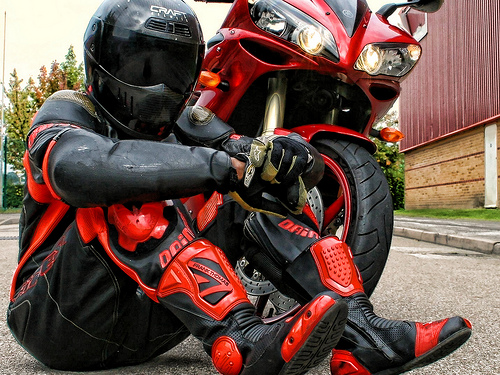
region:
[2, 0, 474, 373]
a very protective suit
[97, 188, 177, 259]
a substantial knee pad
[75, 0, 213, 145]
a helmet that could be a mask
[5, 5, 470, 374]
a person in Halloween colors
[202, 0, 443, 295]
a cycle with its light on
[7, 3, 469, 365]
color coordinated bike and outfit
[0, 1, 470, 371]
a bike rider sits on the pavement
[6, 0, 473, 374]
a motorcycle rider takes a break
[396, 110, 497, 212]
a foundation of unfinished wood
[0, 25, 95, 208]
leaves that are beginning to turn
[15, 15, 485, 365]
motorcyclist seated in front of motorcycle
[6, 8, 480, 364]
biker covered from head to toe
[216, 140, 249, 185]
view of skin between sleeve and glove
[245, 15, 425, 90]
white headlights turned on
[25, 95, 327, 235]
hands touching on extended arms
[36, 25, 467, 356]
biker's outfit matching the colors of motorcycle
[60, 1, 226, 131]
full black helmet covering entire head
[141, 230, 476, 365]
black boots with red embellishments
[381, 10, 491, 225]
corner of building covered in two different materials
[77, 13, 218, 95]
dark goggles spanning across the helmet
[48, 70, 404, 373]
The man is sitting on the ground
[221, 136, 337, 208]
The man has his hand folded.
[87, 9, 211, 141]
The helmet covers the man face.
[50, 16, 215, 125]
The helmet is black.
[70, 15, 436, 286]
The man is sitting next to the motorcycle.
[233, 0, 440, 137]
The motorcycle is red.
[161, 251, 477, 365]
The person is wearing black and red boots.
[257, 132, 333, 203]
The man has on black gloves.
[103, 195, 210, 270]
The man is wearing red knee pads.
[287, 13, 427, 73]
The headlights on the motorcycle is on.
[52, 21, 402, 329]
This person drives the motorcycle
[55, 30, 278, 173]
He wears a helmet for safety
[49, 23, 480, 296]
The outfit matches the bike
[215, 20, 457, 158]
The motorcycle has 4 lights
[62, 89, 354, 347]
His gear is black and red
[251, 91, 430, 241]
The gold bar supports the bike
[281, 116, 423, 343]
The tire is black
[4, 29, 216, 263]
Trees are in the background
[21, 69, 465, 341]
He is in a parking lot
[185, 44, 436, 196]
These lights indicate turns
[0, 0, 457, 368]
Motorcyclist is sitting on the road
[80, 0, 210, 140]
Helmet is black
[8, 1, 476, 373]
Motorcyclist wearing black helmet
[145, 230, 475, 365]
Black and red boots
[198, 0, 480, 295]
Motorcyclist next to motorcycle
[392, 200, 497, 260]
Grass is growing on sidewalk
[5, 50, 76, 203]
Trees behind the motorcyclist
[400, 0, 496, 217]
Building has a red roof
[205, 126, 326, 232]
Motorcyclist wears green gloves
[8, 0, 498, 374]
Helmet cover the face of motorcyclist